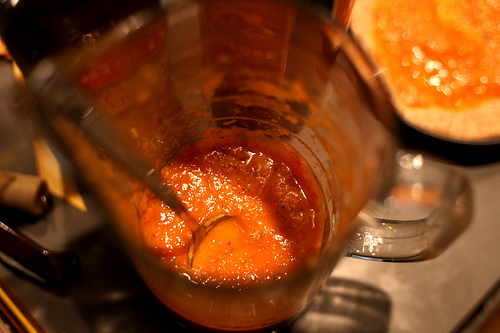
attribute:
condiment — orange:
[137, 122, 315, 284]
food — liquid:
[361, 3, 499, 128]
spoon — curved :
[62, 105, 244, 262]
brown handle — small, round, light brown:
[1, 170, 48, 218]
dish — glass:
[134, 89, 365, 257]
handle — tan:
[5, 172, 56, 217]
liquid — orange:
[193, 143, 313, 255]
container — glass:
[55, 22, 409, 323]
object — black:
[2, 193, 111, 316]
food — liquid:
[132, 148, 312, 266]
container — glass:
[44, 30, 462, 315]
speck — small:
[225, 240, 231, 245]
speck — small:
[280, 203, 285, 207]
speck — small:
[239, 186, 245, 191]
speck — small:
[152, 232, 156, 237]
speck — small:
[299, 206, 304, 211]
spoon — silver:
[25, 60, 235, 273]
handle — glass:
[342, 148, 475, 265]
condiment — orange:
[367, 1, 484, 112]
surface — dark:
[2, 146, 483, 329]